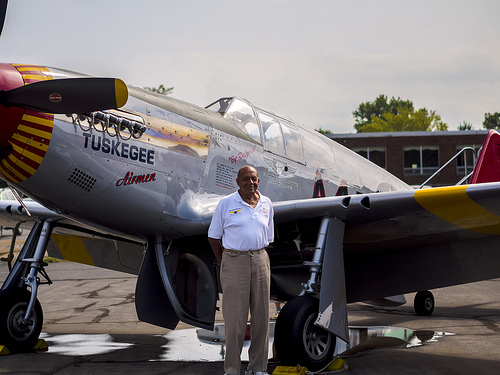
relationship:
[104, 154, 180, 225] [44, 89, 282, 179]
print on jet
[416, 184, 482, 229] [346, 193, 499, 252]
stripe on wing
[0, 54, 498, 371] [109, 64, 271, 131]
jet has cockpit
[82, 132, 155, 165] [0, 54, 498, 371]
lettering on jet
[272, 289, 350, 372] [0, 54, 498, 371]
gear on jet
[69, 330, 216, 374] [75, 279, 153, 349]
puddle on ground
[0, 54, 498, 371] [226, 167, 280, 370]
jet by man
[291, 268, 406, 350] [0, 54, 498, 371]
gear on jet